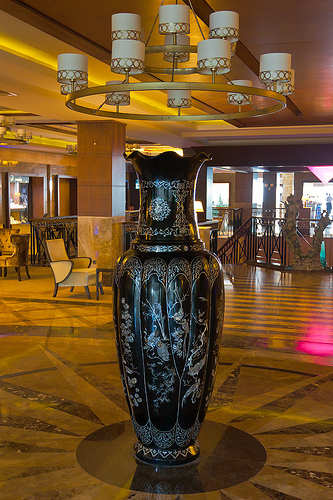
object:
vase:
[111, 149, 226, 468]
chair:
[40, 236, 104, 301]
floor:
[231, 280, 313, 405]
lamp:
[194, 200, 204, 214]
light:
[110, 38, 145, 83]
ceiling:
[215, 1, 333, 128]